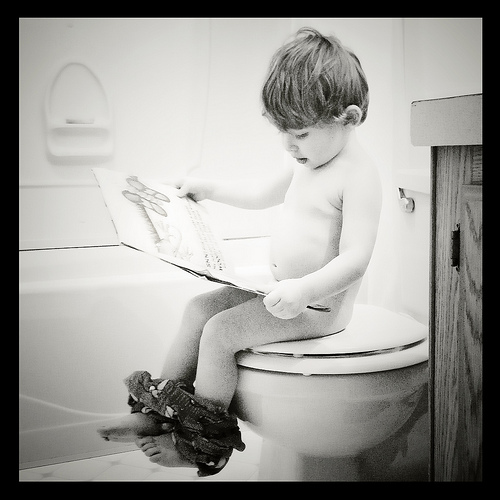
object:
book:
[80, 144, 325, 340]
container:
[38, 51, 124, 163]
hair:
[261, 25, 370, 127]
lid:
[236, 302, 435, 378]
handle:
[390, 184, 418, 216]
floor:
[44, 458, 186, 491]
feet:
[86, 402, 210, 468]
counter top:
[405, 90, 485, 146]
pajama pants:
[120, 371, 241, 470]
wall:
[10, 10, 422, 265]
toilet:
[20, 11, 484, 479]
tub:
[47, 60, 120, 166]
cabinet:
[414, 111, 486, 483]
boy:
[97, 28, 387, 469]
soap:
[58, 107, 106, 134]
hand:
[264, 277, 302, 317]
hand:
[171, 171, 209, 203]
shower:
[17, 15, 289, 251]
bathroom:
[21, 24, 484, 484]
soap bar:
[65, 113, 98, 126]